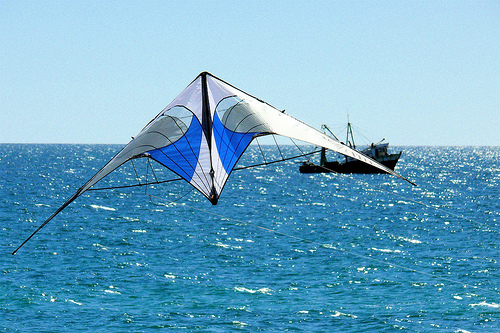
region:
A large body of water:
[0, 149, 487, 317]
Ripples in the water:
[0, 251, 496, 328]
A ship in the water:
[302, 107, 402, 179]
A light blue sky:
[0, 0, 499, 60]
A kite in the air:
[12, 72, 417, 264]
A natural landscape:
[2, 42, 498, 294]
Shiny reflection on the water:
[407, 142, 498, 329]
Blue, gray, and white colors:
[97, 92, 335, 209]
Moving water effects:
[71, 200, 420, 317]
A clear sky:
[4, 14, 499, 70]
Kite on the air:
[10, 61, 430, 276]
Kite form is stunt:
[5, 65, 428, 268]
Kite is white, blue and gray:
[13, 57, 425, 263]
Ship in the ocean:
[287, 111, 405, 191]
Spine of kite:
[192, 61, 228, 209]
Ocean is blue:
[9, 142, 499, 328]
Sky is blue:
[8, 5, 493, 142]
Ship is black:
[296, 113, 408, 183]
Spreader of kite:
[98, 70, 318, 204]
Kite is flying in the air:
[11, 56, 420, 283]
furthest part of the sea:
[429, 147, 456, 160]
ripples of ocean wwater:
[211, 263, 246, 298]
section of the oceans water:
[96, 281, 140, 303]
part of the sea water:
[363, 286, 392, 319]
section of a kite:
[223, 113, 241, 150]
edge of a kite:
[202, 72, 207, 78]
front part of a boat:
[396, 156, 401, 159]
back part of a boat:
[301, 165, 306, 171]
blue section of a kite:
[227, 134, 237, 153]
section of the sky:
[391, 87, 430, 124]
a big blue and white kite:
[18, 62, 423, 291]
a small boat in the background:
[298, 113, 405, 179]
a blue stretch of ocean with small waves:
[3, 133, 495, 325]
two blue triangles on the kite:
[146, 112, 261, 182]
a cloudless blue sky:
[3, 4, 498, 151]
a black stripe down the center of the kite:
[188, 65, 230, 212]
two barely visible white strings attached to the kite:
[180, 133, 495, 316]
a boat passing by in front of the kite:
[291, 116, 407, 183]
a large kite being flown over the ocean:
[20, 51, 422, 284]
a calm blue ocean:
[1, 131, 485, 331]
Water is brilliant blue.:
[2, 140, 498, 331]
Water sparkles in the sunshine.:
[0, 140, 499, 330]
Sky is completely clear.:
[1, 0, 499, 142]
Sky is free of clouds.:
[1, 2, 498, 146]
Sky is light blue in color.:
[1, 1, 498, 144]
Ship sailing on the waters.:
[287, 113, 404, 178]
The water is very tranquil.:
[0, 141, 499, 331]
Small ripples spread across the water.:
[0, 140, 498, 331]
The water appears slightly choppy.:
[0, 139, 499, 331]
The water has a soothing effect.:
[0, 136, 499, 331]